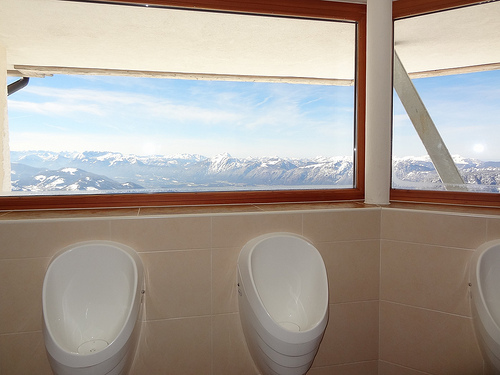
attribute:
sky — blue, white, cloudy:
[9, 75, 497, 165]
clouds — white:
[20, 77, 330, 135]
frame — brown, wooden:
[2, 3, 498, 210]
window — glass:
[1, 3, 493, 185]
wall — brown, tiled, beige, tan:
[13, 216, 498, 372]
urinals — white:
[36, 230, 493, 375]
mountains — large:
[8, 149, 500, 193]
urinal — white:
[40, 237, 141, 373]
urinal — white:
[240, 230, 338, 371]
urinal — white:
[462, 242, 500, 360]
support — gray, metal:
[9, 73, 33, 101]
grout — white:
[10, 221, 484, 373]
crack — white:
[205, 221, 222, 375]